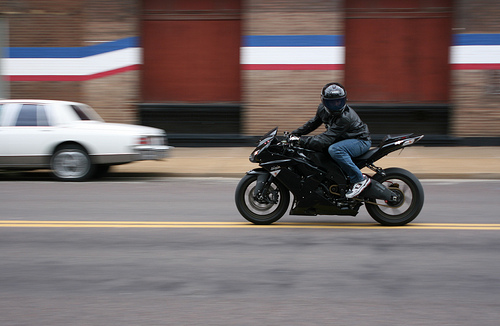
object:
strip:
[240, 35, 345, 71]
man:
[288, 77, 387, 199]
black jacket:
[292, 107, 375, 152]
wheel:
[362, 167, 422, 228]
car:
[0, 95, 179, 183]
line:
[1, 218, 499, 230]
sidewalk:
[117, 145, 499, 187]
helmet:
[315, 82, 351, 115]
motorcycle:
[227, 119, 438, 233]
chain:
[317, 165, 409, 210]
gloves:
[295, 137, 308, 146]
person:
[275, 69, 432, 203]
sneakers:
[340, 173, 376, 201]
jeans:
[328, 136, 371, 186]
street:
[0, 216, 499, 323]